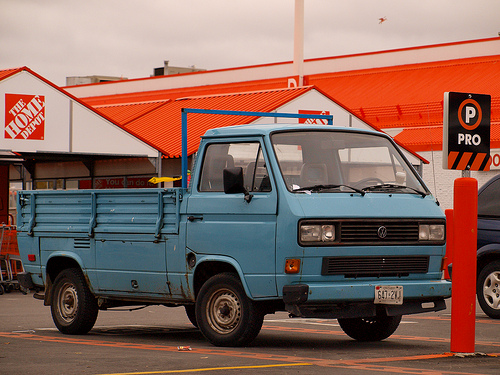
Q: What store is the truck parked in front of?
A: The Home Depot.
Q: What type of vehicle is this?
A: Pickup truck.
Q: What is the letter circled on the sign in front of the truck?
A: P.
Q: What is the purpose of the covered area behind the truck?
A: Cart return.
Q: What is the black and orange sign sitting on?
A: An orange pole.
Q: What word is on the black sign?
A: Pro.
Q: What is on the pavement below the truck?
A: Orange lines.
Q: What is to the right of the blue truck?
A: A dark blue vehicle.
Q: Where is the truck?
A: On the road.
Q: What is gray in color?
A: The sky.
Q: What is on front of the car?
A: A pole.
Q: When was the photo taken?
A: During the daytime.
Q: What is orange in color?
A: The building.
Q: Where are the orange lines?
A: On the ground.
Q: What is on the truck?
A: Tires.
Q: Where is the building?
A: Behind the truck.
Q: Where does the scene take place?
A: At a parking lot.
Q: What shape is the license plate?
A: Rectangular.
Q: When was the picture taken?
A: Daytime.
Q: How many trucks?
A: 1.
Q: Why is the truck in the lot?
A: Parked.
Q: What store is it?
A: Home Depot.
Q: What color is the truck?
A: Blue.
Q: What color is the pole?
A: Orange.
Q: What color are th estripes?
A: Yellow.